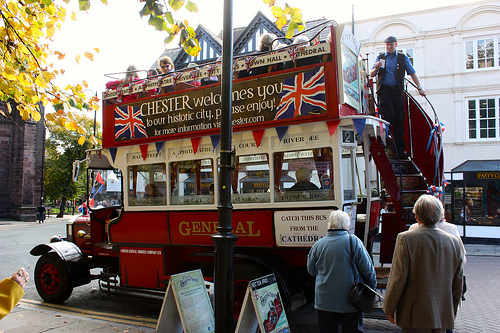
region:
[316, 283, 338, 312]
part of a jumper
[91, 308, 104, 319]
edge of a road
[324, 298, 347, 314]
edge of a swetaer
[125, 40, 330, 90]
People gazing down from atop the vehicle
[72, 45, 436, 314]
A small red bus on the road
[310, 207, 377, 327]
An old woman waiting for the bus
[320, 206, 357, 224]
The woman's hair is short and white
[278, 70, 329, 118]
Union Jack flag on the red vehicle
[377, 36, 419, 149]
A man in blue and black on the stairwell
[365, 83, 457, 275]
A red stairwell winding up the vehicle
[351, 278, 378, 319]
A black purse held by the old woman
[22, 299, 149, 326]
Yellow lines near the curb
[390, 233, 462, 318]
A brown jacket being worn by the man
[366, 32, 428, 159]
a man holding on to a rail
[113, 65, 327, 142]
a sign with writing and two British flags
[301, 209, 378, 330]
a white haired person with a purse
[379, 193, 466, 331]
the back view of a person wearing a suit jacket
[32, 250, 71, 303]
a tire with a red hubcap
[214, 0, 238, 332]
a black light pole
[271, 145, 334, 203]
a man sitting behind a window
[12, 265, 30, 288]
a hand with rings on it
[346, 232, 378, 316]
a black purse slung on a shoulder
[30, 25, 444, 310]
a large tour bus with passengers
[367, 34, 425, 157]
the man on the stairs of the vehicle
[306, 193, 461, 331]
the people standing on the sidewalk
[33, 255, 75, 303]
the front tire on the vehicle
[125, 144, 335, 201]
the windows on the side of the bus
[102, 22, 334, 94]
the people on the second deck of the bus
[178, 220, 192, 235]
the letter G on the bus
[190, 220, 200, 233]
the letter E on the bus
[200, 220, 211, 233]
the letter N on the bus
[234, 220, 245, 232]
the letter A on the bus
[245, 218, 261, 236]
the letter L on the bus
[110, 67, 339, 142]
sign on the side of the bus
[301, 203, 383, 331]
old lady on the sidewalk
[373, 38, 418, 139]
man standing on the stairs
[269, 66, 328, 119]
red, white. and blue flag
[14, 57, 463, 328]
double decker bus on the road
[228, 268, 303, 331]
sign on the sidewalk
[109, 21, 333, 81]
people sitting on top of the bus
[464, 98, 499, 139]
window on the side of the building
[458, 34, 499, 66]
lines on the window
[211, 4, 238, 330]
tall black pole